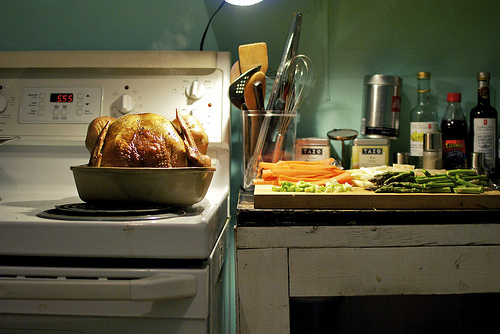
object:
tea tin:
[352, 136, 390, 167]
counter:
[239, 174, 498, 226]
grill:
[48, 201, 182, 222]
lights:
[51, 93, 76, 104]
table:
[235, 162, 499, 331]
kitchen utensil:
[270, 53, 315, 163]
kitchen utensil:
[243, 10, 300, 187]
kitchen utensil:
[252, 79, 266, 128]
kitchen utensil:
[243, 70, 265, 156]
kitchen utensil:
[228, 65, 260, 157]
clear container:
[241, 109, 297, 194]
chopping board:
[244, 144, 498, 209]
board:
[252, 175, 498, 211]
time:
[51, 94, 72, 103]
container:
[326, 128, 359, 165]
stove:
[6, 55, 226, 332]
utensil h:
[229, 41, 273, 145]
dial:
[112, 93, 139, 116]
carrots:
[287, 163, 338, 171]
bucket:
[241, 108, 298, 190]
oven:
[0, 44, 221, 331]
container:
[290, 136, 331, 161]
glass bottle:
[409, 65, 440, 165]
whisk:
[269, 53, 316, 162]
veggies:
[454, 178, 476, 188]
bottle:
[407, 69, 439, 167]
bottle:
[439, 90, 464, 170]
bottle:
[465, 67, 499, 174]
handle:
[0, 275, 196, 299]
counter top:
[235, 181, 498, 223]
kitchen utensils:
[242, 107, 277, 188]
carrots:
[272, 169, 333, 176]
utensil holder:
[238, 105, 298, 190]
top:
[234, 187, 499, 226]